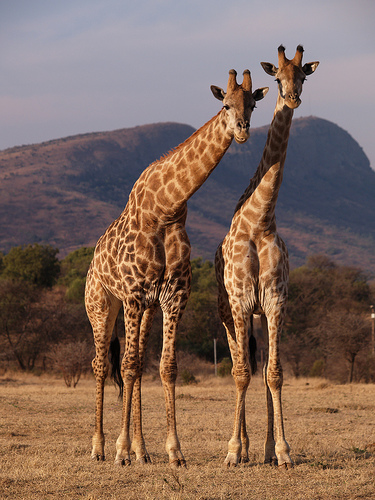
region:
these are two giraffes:
[43, 39, 342, 486]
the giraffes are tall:
[56, 41, 322, 496]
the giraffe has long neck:
[150, 68, 248, 210]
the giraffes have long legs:
[69, 322, 289, 463]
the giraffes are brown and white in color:
[37, 41, 325, 474]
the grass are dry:
[20, 474, 373, 498]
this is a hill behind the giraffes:
[298, 132, 361, 226]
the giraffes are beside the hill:
[298, 270, 365, 370]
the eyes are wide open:
[219, 101, 258, 113]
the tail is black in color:
[106, 332, 124, 367]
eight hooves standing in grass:
[80, 418, 358, 495]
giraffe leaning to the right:
[65, 64, 263, 489]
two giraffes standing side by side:
[68, 31, 336, 479]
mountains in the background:
[8, 85, 368, 209]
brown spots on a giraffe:
[88, 152, 211, 316]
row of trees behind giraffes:
[2, 230, 367, 351]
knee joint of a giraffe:
[222, 342, 299, 392]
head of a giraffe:
[266, 37, 324, 122]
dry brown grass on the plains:
[11, 377, 360, 494]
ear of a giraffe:
[209, 80, 227, 105]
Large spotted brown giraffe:
[215, 20, 346, 448]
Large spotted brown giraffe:
[46, 61, 281, 477]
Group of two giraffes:
[68, 27, 350, 482]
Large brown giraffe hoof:
[215, 414, 249, 479]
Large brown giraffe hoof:
[268, 426, 301, 476]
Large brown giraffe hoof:
[163, 416, 187, 478]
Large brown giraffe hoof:
[131, 431, 151, 471]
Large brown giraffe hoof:
[109, 429, 134, 472]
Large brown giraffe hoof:
[85, 428, 112, 465]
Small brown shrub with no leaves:
[41, 331, 97, 400]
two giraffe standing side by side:
[58, 68, 326, 492]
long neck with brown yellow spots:
[129, 97, 224, 230]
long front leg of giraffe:
[117, 299, 142, 472]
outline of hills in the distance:
[302, 103, 368, 213]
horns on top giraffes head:
[273, 36, 311, 64]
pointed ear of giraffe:
[208, 81, 227, 108]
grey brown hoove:
[222, 445, 241, 470]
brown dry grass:
[13, 394, 78, 497]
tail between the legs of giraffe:
[101, 325, 131, 393]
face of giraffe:
[219, 88, 260, 144]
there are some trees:
[16, 251, 56, 369]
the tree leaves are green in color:
[16, 244, 79, 289]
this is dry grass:
[28, 391, 60, 492]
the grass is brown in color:
[36, 401, 67, 498]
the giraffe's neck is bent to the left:
[149, 62, 259, 218]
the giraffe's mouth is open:
[234, 129, 250, 143]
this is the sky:
[25, 53, 116, 121]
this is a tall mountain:
[312, 116, 358, 261]